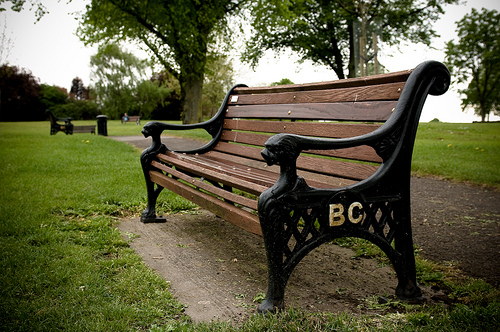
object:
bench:
[140, 60, 450, 311]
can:
[97, 115, 109, 135]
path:
[103, 133, 499, 289]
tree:
[445, 6, 500, 121]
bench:
[51, 117, 96, 135]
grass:
[25, 190, 125, 284]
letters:
[328, 203, 346, 226]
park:
[0, 1, 499, 330]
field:
[6, 149, 93, 297]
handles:
[260, 132, 373, 167]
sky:
[39, 19, 97, 68]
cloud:
[39, 18, 69, 53]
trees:
[0, 0, 253, 124]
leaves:
[103, 16, 128, 36]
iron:
[141, 121, 204, 137]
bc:
[328, 201, 363, 226]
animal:
[260, 139, 296, 165]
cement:
[168, 231, 251, 290]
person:
[123, 113, 130, 124]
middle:
[213, 21, 315, 84]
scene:
[25, 19, 450, 271]